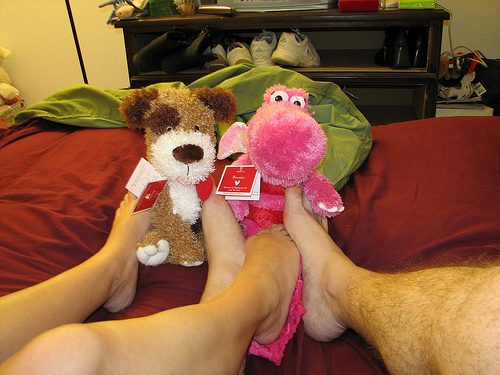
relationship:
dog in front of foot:
[123, 84, 205, 270] [97, 192, 145, 312]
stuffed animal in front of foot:
[217, 83, 347, 238] [284, 186, 349, 343]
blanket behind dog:
[15, 66, 373, 188] [123, 84, 205, 270]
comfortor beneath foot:
[1, 128, 203, 310] [97, 192, 145, 312]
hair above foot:
[355, 268, 499, 374] [284, 186, 349, 343]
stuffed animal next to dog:
[217, 83, 347, 238] [123, 84, 205, 270]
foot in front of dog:
[194, 182, 247, 298] [123, 84, 205, 270]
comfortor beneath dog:
[1, 128, 203, 310] [123, 84, 205, 270]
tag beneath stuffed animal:
[223, 160, 259, 205] [217, 83, 347, 238]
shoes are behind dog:
[254, 33, 322, 72] [123, 84, 205, 270]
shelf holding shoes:
[115, 26, 440, 119] [254, 33, 322, 72]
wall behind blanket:
[2, 2, 131, 107] [15, 66, 373, 188]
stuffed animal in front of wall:
[217, 83, 347, 238] [2, 2, 131, 107]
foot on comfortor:
[194, 182, 247, 298] [1, 128, 203, 310]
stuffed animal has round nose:
[217, 83, 347, 238] [254, 109, 326, 179]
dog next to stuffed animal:
[123, 84, 205, 270] [217, 83, 347, 238]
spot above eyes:
[145, 105, 173, 134] [164, 122, 203, 135]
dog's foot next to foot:
[134, 243, 170, 266] [97, 192, 145, 312]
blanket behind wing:
[15, 66, 373, 188] [217, 122, 251, 161]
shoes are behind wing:
[254, 33, 322, 72] [217, 122, 251, 161]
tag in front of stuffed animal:
[223, 160, 259, 205] [217, 83, 347, 238]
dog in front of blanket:
[123, 84, 205, 270] [15, 66, 373, 188]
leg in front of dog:
[1, 250, 117, 374] [123, 84, 205, 270]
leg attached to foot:
[1, 250, 117, 374] [97, 192, 145, 312]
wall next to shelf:
[2, 2, 131, 107] [115, 26, 440, 119]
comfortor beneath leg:
[1, 128, 203, 310] [1, 250, 117, 374]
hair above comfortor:
[355, 268, 499, 374] [1, 128, 203, 310]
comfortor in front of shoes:
[1, 128, 203, 310] [254, 33, 322, 72]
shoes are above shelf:
[254, 33, 322, 72] [115, 26, 440, 119]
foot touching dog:
[194, 182, 247, 298] [123, 84, 205, 270]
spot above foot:
[145, 105, 173, 134] [97, 192, 145, 312]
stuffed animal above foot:
[217, 83, 347, 238] [284, 186, 349, 343]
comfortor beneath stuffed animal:
[1, 128, 203, 310] [217, 83, 347, 238]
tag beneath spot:
[124, 155, 168, 210] [145, 105, 173, 134]